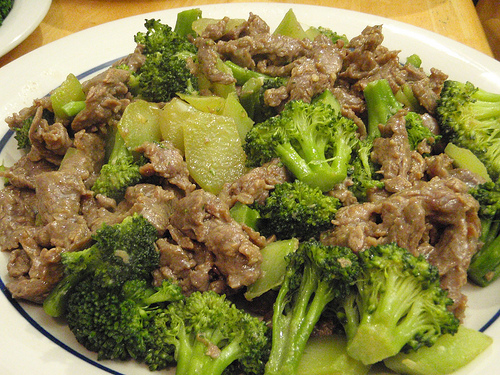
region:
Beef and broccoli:
[1, 7, 496, 372]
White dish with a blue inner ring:
[0, 0, 495, 370]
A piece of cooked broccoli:
[245, 96, 357, 186]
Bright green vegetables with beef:
[0, 6, 495, 371]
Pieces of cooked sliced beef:
[5, 130, 97, 242]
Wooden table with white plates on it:
[0, 0, 495, 75]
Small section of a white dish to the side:
[0, 1, 55, 58]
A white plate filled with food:
[5, 4, 499, 374]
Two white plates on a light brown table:
[1, 0, 498, 370]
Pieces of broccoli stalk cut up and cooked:
[183, 96, 249, 183]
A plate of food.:
[0, 6, 496, 371]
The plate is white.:
[1, 15, 497, 371]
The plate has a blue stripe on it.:
[15, 303, 102, 373]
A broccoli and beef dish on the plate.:
[0, 5, 497, 374]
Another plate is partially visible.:
[0, 0, 56, 62]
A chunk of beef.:
[175, 190, 248, 260]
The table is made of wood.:
[405, 1, 471, 22]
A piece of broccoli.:
[330, 236, 447, 362]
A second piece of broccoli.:
[260, 182, 340, 233]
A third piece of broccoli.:
[244, 100, 355, 185]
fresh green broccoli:
[243, 103, 368, 186]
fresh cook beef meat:
[146, 178, 249, 268]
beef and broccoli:
[119, 25, 428, 310]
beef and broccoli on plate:
[3, 5, 498, 368]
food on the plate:
[6, 3, 498, 373]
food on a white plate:
[0, 3, 499, 370]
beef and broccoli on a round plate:
[0, 0, 499, 374]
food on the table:
[0, 0, 499, 372]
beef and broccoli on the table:
[1, 1, 498, 373]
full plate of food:
[2, 0, 497, 373]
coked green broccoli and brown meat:
[82, 97, 162, 204]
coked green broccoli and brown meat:
[58, 219, 168, 319]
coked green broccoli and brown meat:
[93, 197, 216, 327]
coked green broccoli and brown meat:
[168, 210, 286, 297]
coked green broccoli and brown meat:
[251, 232, 338, 335]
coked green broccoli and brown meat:
[256, 155, 321, 238]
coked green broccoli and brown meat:
[258, 99, 358, 182]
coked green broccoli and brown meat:
[317, 228, 441, 370]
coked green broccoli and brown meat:
[349, 111, 448, 223]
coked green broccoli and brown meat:
[133, 30, 263, 119]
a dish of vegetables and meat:
[2, 2, 497, 372]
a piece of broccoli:
[236, 92, 374, 194]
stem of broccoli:
[343, 293, 412, 370]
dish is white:
[9, 3, 499, 374]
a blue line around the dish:
[3, 7, 499, 374]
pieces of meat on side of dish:
[7, 135, 89, 269]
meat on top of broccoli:
[133, 163, 263, 300]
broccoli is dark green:
[63, 275, 152, 359]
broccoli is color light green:
[176, 293, 264, 353]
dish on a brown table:
[1, 0, 498, 374]